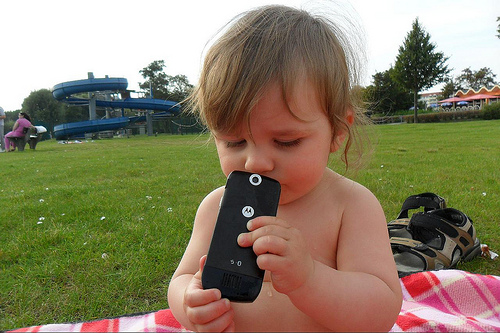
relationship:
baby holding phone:
[165, 4, 403, 332] [200, 170, 282, 304]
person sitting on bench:
[3, 111, 32, 152] [5, 124, 40, 152]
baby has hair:
[165, 4, 403, 332] [181, 3, 379, 171]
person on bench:
[3, 111, 32, 152] [3, 94, 71, 166]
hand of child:
[237, 207, 417, 331] [135, 67, 436, 297]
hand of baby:
[237, 215, 314, 293] [165, 4, 403, 332]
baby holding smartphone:
[165, 4, 403, 332] [189, 160, 294, 289]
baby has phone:
[115, 8, 416, 285] [161, 139, 311, 319]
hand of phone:
[237, 215, 314, 293] [194, 139, 314, 331]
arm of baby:
[303, 175, 407, 271] [89, 8, 451, 320]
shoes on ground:
[373, 153, 483, 300] [14, 88, 461, 311]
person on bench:
[9, 98, 71, 208] [13, 96, 69, 157]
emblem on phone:
[234, 185, 256, 228] [140, 150, 285, 296]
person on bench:
[3, 111, 32, 152] [5, 110, 56, 156]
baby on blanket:
[165, 4, 403, 332] [77, 257, 484, 321]